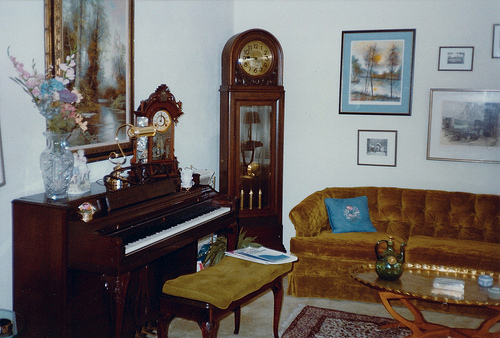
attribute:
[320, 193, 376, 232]
pillow — blue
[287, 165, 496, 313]
couch — brown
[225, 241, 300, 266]
papers — Stack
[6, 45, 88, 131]
flowers — Light colored 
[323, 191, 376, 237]
pillow — blue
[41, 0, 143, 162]
frame — black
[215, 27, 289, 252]
clock — grandfather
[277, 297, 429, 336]
rug — white colored, Red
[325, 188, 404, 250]
pillow — blue, brown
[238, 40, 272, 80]
clock — Grandfather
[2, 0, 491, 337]
room — corner 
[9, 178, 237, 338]
piano — top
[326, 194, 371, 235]
pillow — blue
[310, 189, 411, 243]
pillow — blue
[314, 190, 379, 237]
pillow —  blue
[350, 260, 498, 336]
coffee table — wooden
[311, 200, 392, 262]
pillow — Blue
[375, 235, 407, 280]
teapot — Glass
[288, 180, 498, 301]
couch — brown 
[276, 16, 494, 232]
wall — painted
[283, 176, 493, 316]
couch — dark yellow